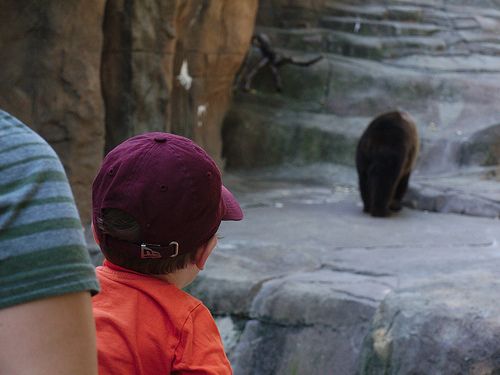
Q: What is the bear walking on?
A: Rocks.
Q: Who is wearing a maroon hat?
A: A boy.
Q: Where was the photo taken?
A: Zoo.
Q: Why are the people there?
A: To see the animals.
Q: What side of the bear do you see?
A: Backside.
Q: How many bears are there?
A: One.